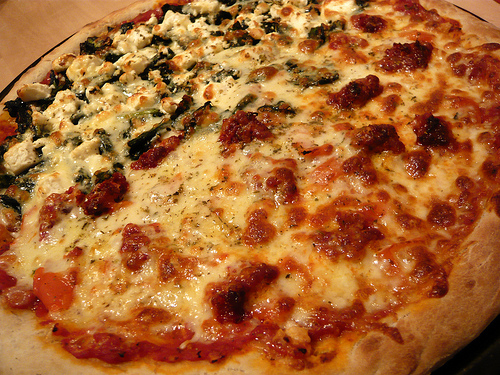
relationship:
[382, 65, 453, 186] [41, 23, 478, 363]
cheese on pizza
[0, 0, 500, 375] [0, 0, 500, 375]
cheese on cheesy pizza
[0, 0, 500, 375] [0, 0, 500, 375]
cheese on a cheesy pizza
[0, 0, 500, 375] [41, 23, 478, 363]
cheese on a pizza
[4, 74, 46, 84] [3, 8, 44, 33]
pan on table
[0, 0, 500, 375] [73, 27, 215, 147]
cheesy pizza with spinach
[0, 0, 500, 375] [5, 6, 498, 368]
cheesy pizza has halves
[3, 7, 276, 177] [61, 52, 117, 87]
cheesy pizza with chicken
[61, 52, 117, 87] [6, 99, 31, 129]
chicken and spinach